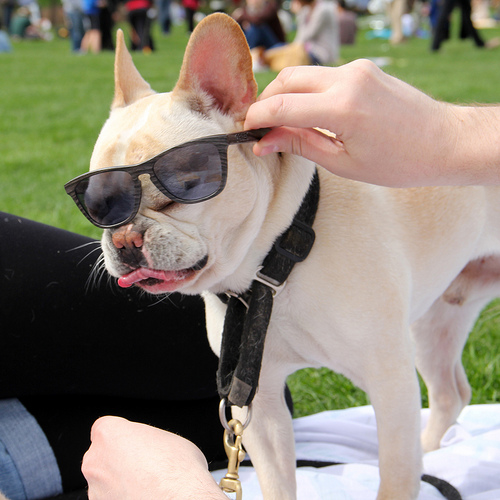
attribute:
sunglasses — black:
[64, 127, 272, 229]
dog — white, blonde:
[65, 11, 499, 499]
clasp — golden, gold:
[219, 418, 246, 499]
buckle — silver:
[215, 265, 288, 313]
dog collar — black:
[215, 164, 320, 409]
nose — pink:
[111, 223, 149, 266]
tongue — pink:
[117, 267, 186, 288]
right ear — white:
[110, 28, 158, 111]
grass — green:
[0, 0, 500, 420]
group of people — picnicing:
[0, 0, 500, 68]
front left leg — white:
[307, 226, 424, 499]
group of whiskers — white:
[65, 240, 122, 296]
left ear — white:
[171, 11, 259, 129]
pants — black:
[97, 8, 115, 51]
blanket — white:
[210, 403, 500, 499]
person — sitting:
[271, 0, 343, 66]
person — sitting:
[232, 0, 287, 49]